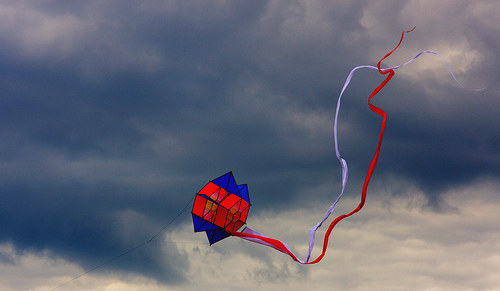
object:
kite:
[192, 27, 484, 267]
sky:
[0, 0, 498, 291]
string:
[235, 27, 489, 266]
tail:
[232, 26, 486, 266]